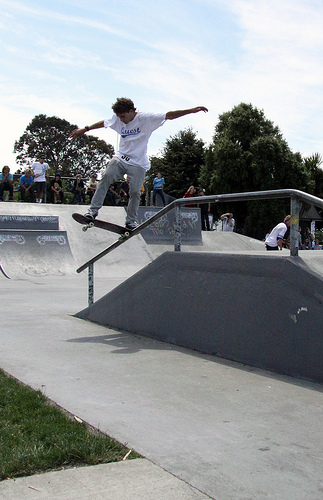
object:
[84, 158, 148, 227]
grey pants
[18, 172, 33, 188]
blue shirt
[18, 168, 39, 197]
sitting down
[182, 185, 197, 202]
red shirt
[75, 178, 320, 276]
skateboarding rail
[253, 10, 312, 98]
clouds are white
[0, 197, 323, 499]
ground is grey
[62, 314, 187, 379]
shadow falls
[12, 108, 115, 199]
trees are found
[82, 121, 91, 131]
black watch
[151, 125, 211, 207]
trees are green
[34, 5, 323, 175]
part of the sky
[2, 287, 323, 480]
part of a footpath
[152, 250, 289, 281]
part of a line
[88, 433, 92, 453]
some grass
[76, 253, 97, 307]
part of a metal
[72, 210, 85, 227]
edge of a skateboard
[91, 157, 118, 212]
part of a trouser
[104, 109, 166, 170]
white top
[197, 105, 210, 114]
left hand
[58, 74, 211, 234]
skater doing a trick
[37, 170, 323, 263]
grinding on a rail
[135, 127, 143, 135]
blue lettering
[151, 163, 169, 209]
people watching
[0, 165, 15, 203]
man in glasses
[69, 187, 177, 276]
down railing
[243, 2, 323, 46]
clouds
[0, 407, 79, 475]
ground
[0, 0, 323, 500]
skate park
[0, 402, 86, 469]
field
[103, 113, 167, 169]
shirt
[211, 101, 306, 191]
trees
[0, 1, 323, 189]
sky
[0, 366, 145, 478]
grass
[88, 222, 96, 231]
wheels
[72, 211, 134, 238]
skateboard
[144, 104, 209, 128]
arms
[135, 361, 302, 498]
cement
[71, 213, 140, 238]
board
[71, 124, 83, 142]
hand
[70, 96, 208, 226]
boy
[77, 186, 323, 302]
railing